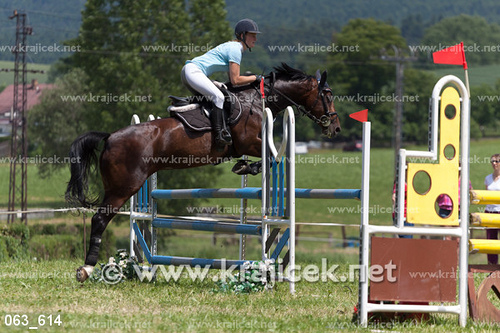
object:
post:
[150, 188, 361, 201]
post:
[152, 217, 261, 235]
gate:
[128, 105, 297, 294]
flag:
[432, 41, 467, 70]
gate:
[360, 75, 471, 328]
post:
[152, 255, 259, 271]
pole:
[360, 122, 371, 328]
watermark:
[101, 263, 123, 286]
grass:
[0, 137, 500, 333]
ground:
[435, 63, 498, 86]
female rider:
[181, 19, 265, 145]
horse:
[64, 62, 341, 284]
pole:
[397, 149, 407, 228]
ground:
[0, 137, 500, 333]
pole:
[5, 12, 28, 226]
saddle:
[167, 87, 243, 133]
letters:
[133, 258, 402, 288]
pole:
[394, 60, 403, 226]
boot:
[210, 103, 223, 144]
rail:
[270, 187, 361, 199]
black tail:
[61, 130, 110, 218]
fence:
[129, 74, 499, 329]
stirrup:
[215, 110, 232, 145]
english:
[186, 94, 278, 104]